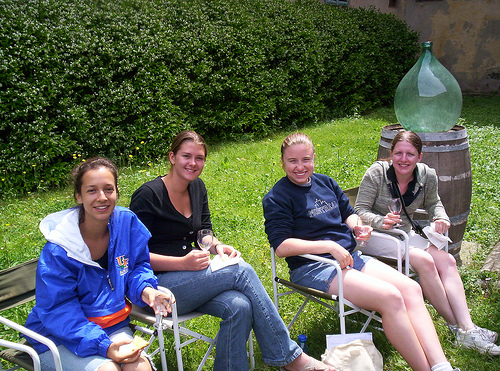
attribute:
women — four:
[62, 149, 492, 349]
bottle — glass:
[396, 51, 482, 122]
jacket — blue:
[54, 224, 166, 339]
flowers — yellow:
[228, 87, 268, 250]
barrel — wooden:
[447, 123, 464, 202]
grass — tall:
[7, 214, 34, 280]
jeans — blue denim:
[205, 248, 257, 339]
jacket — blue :
[29, 198, 159, 332]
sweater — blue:
[260, 172, 359, 271]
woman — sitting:
[20, 155, 174, 369]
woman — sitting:
[127, 126, 339, 369]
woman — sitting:
[260, 130, 459, 370]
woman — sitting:
[350, 128, 484, 354]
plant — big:
[0, 1, 424, 198]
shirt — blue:
[260, 169, 360, 269]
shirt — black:
[128, 172, 216, 274]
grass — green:
[1, 98, 484, 368]